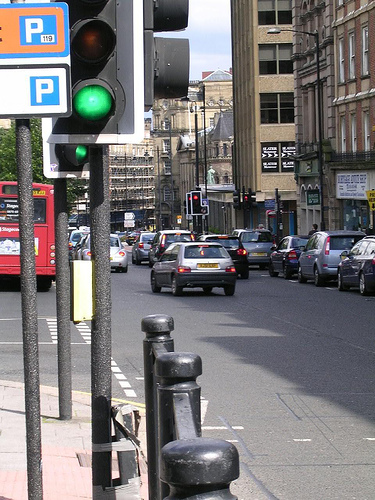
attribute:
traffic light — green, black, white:
[71, 81, 117, 126]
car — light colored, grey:
[151, 240, 237, 295]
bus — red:
[0, 181, 55, 293]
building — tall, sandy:
[232, 0, 296, 232]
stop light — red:
[191, 193, 199, 203]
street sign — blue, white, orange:
[0, 3, 71, 118]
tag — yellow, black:
[195, 262, 222, 270]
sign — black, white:
[260, 143, 296, 175]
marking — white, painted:
[199, 425, 247, 430]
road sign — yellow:
[363, 189, 375, 212]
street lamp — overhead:
[265, 27, 283, 35]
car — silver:
[297, 230, 366, 288]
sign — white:
[334, 172, 369, 199]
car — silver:
[76, 232, 128, 272]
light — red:
[178, 267, 191, 275]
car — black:
[198, 234, 249, 281]